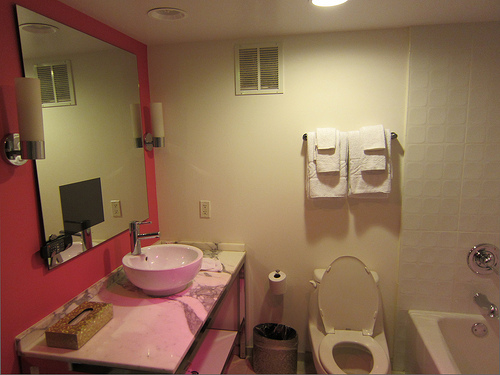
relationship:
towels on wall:
[295, 129, 400, 204] [148, 21, 499, 371]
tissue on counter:
[196, 251, 228, 277] [11, 224, 265, 371]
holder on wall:
[42, 234, 68, 267] [148, 21, 499, 371]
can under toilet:
[242, 318, 307, 374] [294, 252, 414, 373]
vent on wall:
[229, 36, 292, 106] [148, 21, 499, 371]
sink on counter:
[119, 241, 213, 296] [11, 224, 265, 371]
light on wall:
[143, 94, 169, 159] [148, 21, 499, 371]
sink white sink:
[119, 241, 209, 296] [119, 241, 213, 296]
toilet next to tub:
[294, 252, 414, 373] [397, 291, 497, 370]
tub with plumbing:
[397, 291, 497, 370] [464, 249, 499, 345]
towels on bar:
[295, 129, 400, 204] [296, 127, 402, 145]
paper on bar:
[266, 263, 293, 298] [296, 127, 402, 145]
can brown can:
[251, 319, 300, 372] [242, 318, 307, 374]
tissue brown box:
[196, 251, 228, 277] [39, 296, 128, 351]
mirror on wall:
[8, 6, 171, 260] [148, 21, 499, 371]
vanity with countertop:
[19, 231, 258, 368] [11, 234, 264, 374]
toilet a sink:
[294, 252, 414, 373] [119, 241, 209, 296]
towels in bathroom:
[295, 129, 400, 204] [2, 2, 499, 369]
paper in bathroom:
[266, 263, 293, 298] [2, 2, 499, 369]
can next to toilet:
[251, 319, 300, 372] [294, 252, 414, 373]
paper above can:
[266, 263, 293, 298] [242, 318, 307, 374]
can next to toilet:
[242, 318, 307, 374] [294, 252, 414, 373]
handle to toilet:
[309, 280, 319, 291] [294, 252, 414, 373]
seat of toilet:
[311, 254, 381, 337] [294, 252, 414, 373]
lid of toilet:
[315, 252, 381, 341] [294, 252, 414, 373]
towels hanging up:
[295, 129, 400, 204] [305, 116, 396, 176]